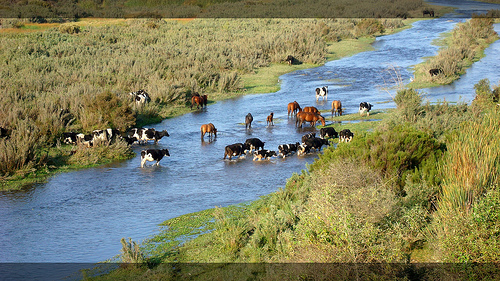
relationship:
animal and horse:
[314, 85, 329, 102] [199, 122, 218, 144]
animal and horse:
[139, 148, 171, 169] [196, 117, 226, 144]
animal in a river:
[139, 148, 171, 169] [0, 1, 498, 279]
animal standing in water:
[358, 101, 374, 117] [38, 50, 456, 242]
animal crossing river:
[223, 142, 248, 161] [0, 1, 498, 279]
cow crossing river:
[242, 137, 266, 151] [0, 1, 498, 279]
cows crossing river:
[252, 145, 277, 163] [0, 1, 498, 279]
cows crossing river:
[299, 136, 329, 156] [0, 1, 498, 279]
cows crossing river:
[275, 141, 302, 161] [0, 1, 498, 279]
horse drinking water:
[289, 106, 336, 128] [313, 37, 395, 97]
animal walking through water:
[223, 142, 248, 161] [6, 23, 486, 267]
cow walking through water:
[240, 137, 265, 152] [6, 23, 486, 267]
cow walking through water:
[335, 125, 355, 147] [6, 23, 486, 267]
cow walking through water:
[317, 127, 337, 147] [6, 23, 486, 267]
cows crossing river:
[252, 149, 278, 162] [9, 123, 260, 262]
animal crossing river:
[139, 148, 171, 169] [9, 123, 260, 262]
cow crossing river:
[337, 128, 354, 144] [9, 123, 260, 262]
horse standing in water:
[197, 120, 218, 144] [6, 23, 486, 267]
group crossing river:
[219, 122, 356, 162] [0, 1, 498, 279]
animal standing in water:
[139, 148, 171, 169] [33, 40, 411, 258]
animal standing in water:
[129, 144, 181, 174] [11, 158, 302, 238]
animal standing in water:
[199, 120, 219, 142] [131, 100, 315, 177]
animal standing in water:
[139, 148, 171, 169] [131, 100, 315, 177]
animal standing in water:
[313, 83, 330, 100] [131, 100, 315, 177]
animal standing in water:
[265, 110, 277, 126] [131, 100, 315, 177]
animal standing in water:
[223, 142, 248, 161] [40, 177, 150, 236]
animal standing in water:
[314, 85, 329, 102] [98, 94, 352, 184]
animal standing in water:
[242, 111, 254, 131] [98, 94, 352, 184]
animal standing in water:
[357, 103, 373, 117] [98, 94, 352, 184]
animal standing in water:
[266, 111, 275, 126] [0, 1, 499, 278]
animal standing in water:
[223, 143, 253, 164] [149, 101, 348, 190]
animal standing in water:
[139, 148, 171, 169] [149, 101, 348, 190]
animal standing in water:
[199, 122, 218, 142] [149, 101, 348, 190]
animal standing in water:
[190, 93, 209, 110] [149, 101, 348, 190]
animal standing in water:
[358, 101, 374, 117] [6, 23, 486, 267]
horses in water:
[286, 95, 327, 131] [32, 199, 117, 249]